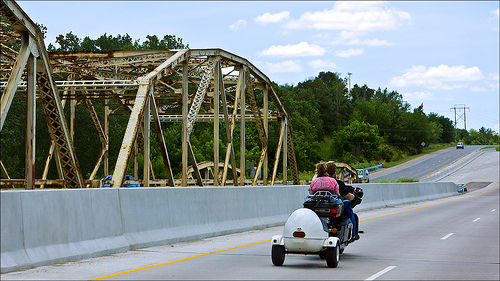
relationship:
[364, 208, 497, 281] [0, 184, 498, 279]
line on road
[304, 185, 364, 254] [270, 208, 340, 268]
motorcyle has a trailer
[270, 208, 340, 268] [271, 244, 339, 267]
trailer has wheels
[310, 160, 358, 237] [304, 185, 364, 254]
people on motorcyle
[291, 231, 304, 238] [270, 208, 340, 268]
tail light on trailer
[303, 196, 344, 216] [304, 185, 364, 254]
storage bin on motorcyle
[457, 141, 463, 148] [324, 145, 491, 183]
car driving on road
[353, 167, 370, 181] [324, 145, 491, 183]
car driving on road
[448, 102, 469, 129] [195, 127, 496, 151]
structure holding power cables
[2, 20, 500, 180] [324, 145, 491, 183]
trees beside road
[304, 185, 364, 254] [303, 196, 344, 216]
motorcyle towing a storage bin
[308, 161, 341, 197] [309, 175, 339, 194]
woman wearing a shirt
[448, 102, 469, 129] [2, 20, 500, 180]
structure by trees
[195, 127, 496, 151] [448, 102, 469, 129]
power cables by structure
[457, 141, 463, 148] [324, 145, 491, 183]
car on road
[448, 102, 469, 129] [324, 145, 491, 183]
structure by road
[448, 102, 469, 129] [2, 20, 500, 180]
structure beside trees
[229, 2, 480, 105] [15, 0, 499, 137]
clouds in sky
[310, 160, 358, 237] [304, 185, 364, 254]
people riding motorcyle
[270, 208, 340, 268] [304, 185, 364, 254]
trailer on motorcyle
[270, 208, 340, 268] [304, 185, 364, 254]
trailer hooked up to motorcyle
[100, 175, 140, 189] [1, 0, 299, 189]
car on bridge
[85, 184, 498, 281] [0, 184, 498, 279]
line on road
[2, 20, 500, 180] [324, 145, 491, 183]
trees next to road